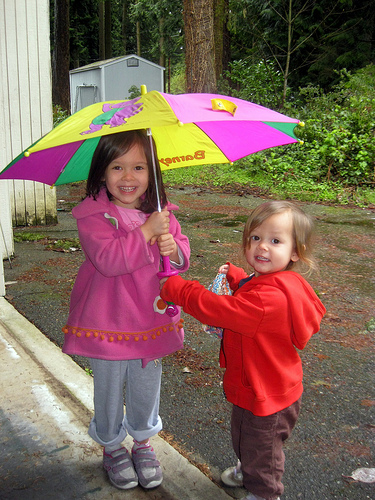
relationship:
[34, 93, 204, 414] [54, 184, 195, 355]
girl wearing coat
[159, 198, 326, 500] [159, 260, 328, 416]
kid wearing jacket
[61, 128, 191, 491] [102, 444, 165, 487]
girl wearing athletic shoes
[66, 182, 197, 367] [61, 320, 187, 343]
coat has fringe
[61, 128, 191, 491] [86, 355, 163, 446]
girl wearing pants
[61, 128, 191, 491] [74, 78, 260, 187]
girl holding umbrella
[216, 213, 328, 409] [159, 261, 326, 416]
child wearing jacket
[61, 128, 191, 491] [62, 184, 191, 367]
girl wearing coat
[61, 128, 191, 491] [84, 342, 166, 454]
girl wearing pants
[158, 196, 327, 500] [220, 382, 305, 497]
child wearing pants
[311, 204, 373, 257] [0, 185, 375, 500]
moss on ground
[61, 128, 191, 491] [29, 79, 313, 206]
girl holding umbrella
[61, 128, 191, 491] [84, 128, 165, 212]
girl with hair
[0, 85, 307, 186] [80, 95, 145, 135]
umbrella with barney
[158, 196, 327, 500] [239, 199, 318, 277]
child with hair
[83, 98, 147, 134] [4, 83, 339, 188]
barney on umbrella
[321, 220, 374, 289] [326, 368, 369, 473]
puddles on ground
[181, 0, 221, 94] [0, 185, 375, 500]
trunk across ground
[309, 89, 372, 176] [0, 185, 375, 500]
green trees next to ground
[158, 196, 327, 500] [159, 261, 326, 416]
child wearing a jacket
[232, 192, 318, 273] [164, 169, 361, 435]
head of kid